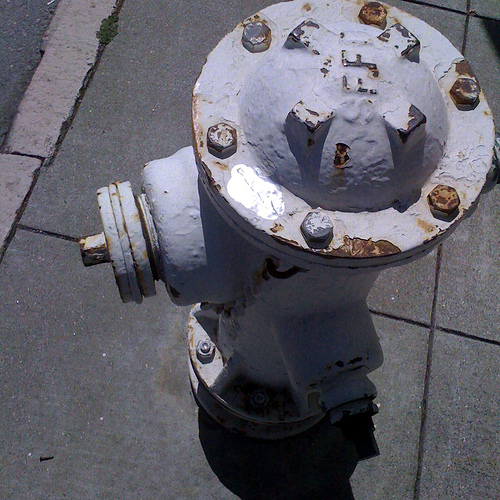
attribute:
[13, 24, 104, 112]
surface — asphalt, street's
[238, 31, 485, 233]
top — metal 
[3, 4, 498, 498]
sidewalk — cement